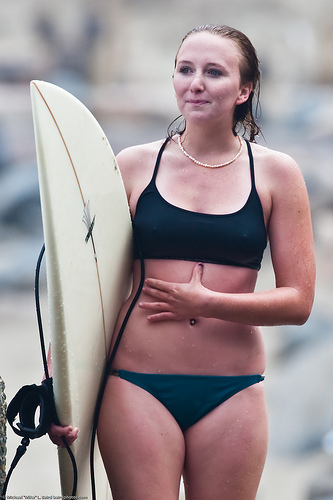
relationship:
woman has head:
[122, 31, 255, 488] [177, 30, 247, 138]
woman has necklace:
[122, 31, 255, 488] [179, 150, 243, 167]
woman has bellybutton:
[122, 31, 255, 488] [189, 318, 194, 327]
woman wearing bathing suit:
[122, 31, 255, 488] [135, 197, 259, 415]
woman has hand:
[122, 31, 255, 488] [149, 289, 185, 317]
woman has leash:
[122, 31, 255, 488] [116, 311, 126, 354]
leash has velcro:
[116, 311, 126, 354] [26, 397, 34, 424]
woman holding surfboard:
[122, 31, 255, 488] [63, 155, 113, 329]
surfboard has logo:
[63, 155, 113, 329] [85, 209, 95, 228]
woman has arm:
[122, 31, 255, 488] [282, 199, 309, 287]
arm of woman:
[282, 199, 309, 287] [122, 31, 255, 488]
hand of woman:
[149, 289, 185, 317] [122, 31, 255, 488]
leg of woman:
[204, 427, 251, 488] [122, 31, 255, 488]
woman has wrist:
[122, 31, 255, 488] [205, 295, 211, 314]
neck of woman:
[206, 135, 212, 147] [122, 31, 255, 488]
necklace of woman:
[179, 150, 243, 167] [122, 31, 255, 488]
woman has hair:
[122, 31, 255, 488] [248, 62, 255, 74]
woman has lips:
[122, 31, 255, 488] [184, 100, 209, 105]